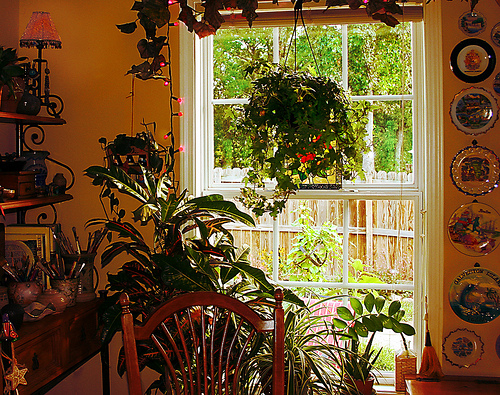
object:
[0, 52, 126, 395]
shelf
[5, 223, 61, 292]
frame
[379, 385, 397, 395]
ground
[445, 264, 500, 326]
plates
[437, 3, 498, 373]
wall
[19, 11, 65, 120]
holder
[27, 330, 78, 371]
dark wood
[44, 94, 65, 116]
black iron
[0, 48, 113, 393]
buffet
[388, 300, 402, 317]
leaves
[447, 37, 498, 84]
plate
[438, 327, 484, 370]
plate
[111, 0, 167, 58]
plants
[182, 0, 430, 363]
door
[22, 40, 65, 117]
base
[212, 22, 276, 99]
window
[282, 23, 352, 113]
window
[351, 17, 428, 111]
window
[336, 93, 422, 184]
window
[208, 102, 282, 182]
window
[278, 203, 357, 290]
window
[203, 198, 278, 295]
window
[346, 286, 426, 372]
window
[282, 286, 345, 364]
window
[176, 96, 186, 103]
lights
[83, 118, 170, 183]
plant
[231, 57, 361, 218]
hanging plant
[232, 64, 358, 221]
flowers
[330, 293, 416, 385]
flowers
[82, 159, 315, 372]
flowers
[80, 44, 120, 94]
wall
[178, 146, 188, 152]
lights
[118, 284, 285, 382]
wood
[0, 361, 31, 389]
star decoration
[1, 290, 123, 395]
table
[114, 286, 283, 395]
back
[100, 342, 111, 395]
leg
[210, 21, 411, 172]
trees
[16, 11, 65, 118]
lamp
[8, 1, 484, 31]
cieling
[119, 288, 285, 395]
chair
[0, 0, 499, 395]
photo